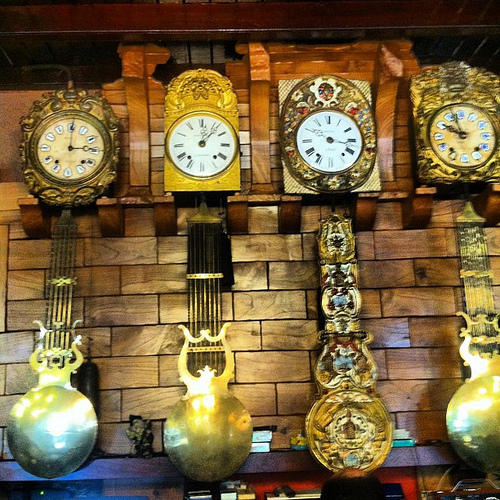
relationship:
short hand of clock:
[333, 137, 343, 142] [276, 74, 403, 475]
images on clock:
[322, 400, 376, 450] [276, 74, 403, 475]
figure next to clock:
[125, 412, 161, 461] [161, 62, 258, 487]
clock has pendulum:
[160, 65, 247, 196] [170, 201, 240, 476]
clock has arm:
[161, 62, 258, 487] [203, 129, 215, 139]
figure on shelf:
[125, 412, 161, 461] [66, 429, 477, 495]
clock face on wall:
[19, 85, 123, 206] [0, 197, 500, 461]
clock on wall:
[164, 65, 248, 195] [0, 197, 500, 461]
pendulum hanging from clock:
[3, 214, 103, 478] [23, 78, 125, 212]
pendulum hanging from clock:
[163, 197, 259, 483] [164, 65, 248, 195]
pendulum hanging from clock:
[303, 221, 397, 476] [279, 71, 380, 194]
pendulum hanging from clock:
[303, 203, 395, 475] [408, 57, 498, 187]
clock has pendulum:
[6, 79, 123, 477] [6, 208, 110, 477]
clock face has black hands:
[19, 84, 123, 206] [66, 139, 103, 154]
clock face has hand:
[19, 84, 123, 206] [65, 142, 92, 153]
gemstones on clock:
[309, 80, 343, 111] [283, 78, 390, 190]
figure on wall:
[125, 413, 157, 461] [0, 197, 500, 461]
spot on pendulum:
[185, 370, 218, 416] [177, 228, 256, 467]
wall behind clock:
[3, 2, 499, 458] [16, 75, 126, 214]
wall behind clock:
[3, 2, 499, 458] [164, 65, 248, 195]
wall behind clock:
[3, 2, 499, 458] [279, 71, 380, 194]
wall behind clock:
[3, 2, 499, 458] [408, 57, 498, 187]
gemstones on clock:
[309, 80, 336, 114] [272, 75, 381, 193]